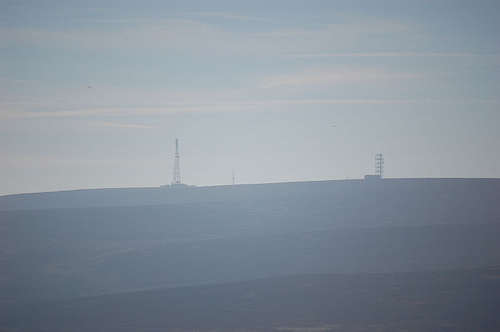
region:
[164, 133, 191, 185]
tall cell phone tower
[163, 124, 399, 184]
three structures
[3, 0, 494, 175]
cloudy blue sky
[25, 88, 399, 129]
long and thin cloud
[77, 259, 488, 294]
ripple in the ground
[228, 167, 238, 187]
very small structure off in the distance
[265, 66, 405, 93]
white and fluffy cloud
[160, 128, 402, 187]
the structure on the left is the tallest of the structures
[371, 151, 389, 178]
structure is gray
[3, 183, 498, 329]
the ground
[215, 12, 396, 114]
Light blue sky with thin pink clouds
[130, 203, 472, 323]
Dark hilly landscape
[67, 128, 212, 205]
Cell tower standing alone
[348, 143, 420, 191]
Small building and power line.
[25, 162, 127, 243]
Hilly terrain against the clear horizon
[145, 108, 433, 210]
One cell tower and one pole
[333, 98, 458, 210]
Small building with power pole nearby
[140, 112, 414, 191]
Cell tower standing above the power pole and small structure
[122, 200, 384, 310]
Dimly lite hilly terrain.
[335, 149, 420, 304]
Small building overlooking hilly landscape.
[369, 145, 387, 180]
a grid tower in the distance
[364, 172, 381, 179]
the base of a grid tower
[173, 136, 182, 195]
a tall telephone tower in the distance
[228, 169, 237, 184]
a short telephone tower in the distance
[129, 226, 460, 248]
a ride in the landscape between two ridges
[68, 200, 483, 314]
three ridges in the hills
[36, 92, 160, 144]
wispy clouds in a blue sky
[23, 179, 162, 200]
an area where the hill meets the skyline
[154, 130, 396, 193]
three towers in the distance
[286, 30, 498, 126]
clouds that look like white lines in the sky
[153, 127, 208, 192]
Electric Power Tower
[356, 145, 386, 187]
Small electric power tower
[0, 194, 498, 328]
Gray hazy dry field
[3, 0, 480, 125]
Sky with orange blue patterns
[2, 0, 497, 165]
Foggy sky with orange yellow clouds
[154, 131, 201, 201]
Electric metal tower with electricity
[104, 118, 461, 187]
Horizon of small objects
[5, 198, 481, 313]
Ascending hill of fog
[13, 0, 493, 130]
Partial view of clouded sky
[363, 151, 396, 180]
Tower with many satellites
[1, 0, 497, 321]
Photo was taken in the daytime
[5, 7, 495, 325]
Photo was taken outdoors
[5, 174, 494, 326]
Ground has a serials of hills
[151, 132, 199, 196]
A large object is in the background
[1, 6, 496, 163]
Sky has a few clouds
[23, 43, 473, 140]
The clouds are long in shape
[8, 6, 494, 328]
The photo has a light blue colored hue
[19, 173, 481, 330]
There are four visible hills in this picture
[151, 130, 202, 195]
Large object is in shadow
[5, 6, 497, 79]
The sky is light blue and gray